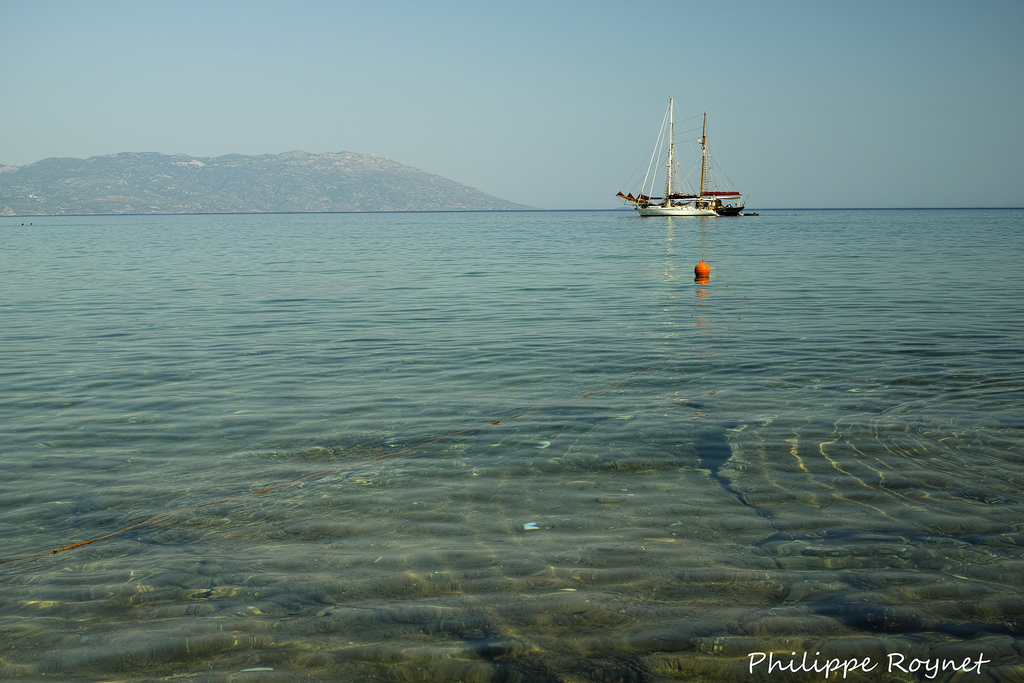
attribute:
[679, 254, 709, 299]
buoy — red, round, orange, floating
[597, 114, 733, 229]
boat — single, white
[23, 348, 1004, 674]
water — placid, clear, calm, shallow, rippling, blue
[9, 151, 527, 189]
hill — treeless, in background, small, on horizon, in distance, sloped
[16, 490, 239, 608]
stick — skinny, floating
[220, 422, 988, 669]
rocks — submerged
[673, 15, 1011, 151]
sky — clear, foggy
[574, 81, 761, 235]
ship — dark, anchored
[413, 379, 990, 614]
ripples — small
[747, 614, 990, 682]
signature — on photo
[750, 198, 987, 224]
horizon — calm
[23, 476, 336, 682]
stones — submerged